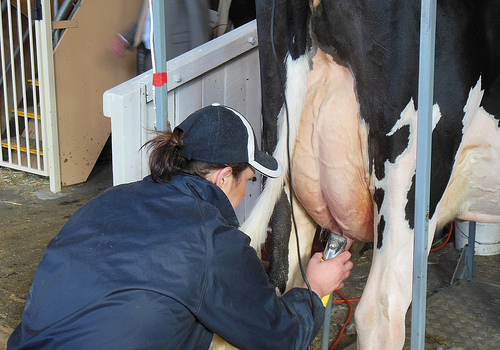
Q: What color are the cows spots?
A: Black.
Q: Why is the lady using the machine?
A: For milk.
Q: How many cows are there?
A: One.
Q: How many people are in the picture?
A: Two.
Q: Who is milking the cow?
A: A lady.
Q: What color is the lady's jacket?
A: Blue.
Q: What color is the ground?
A: Grey.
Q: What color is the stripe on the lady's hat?
A: White.